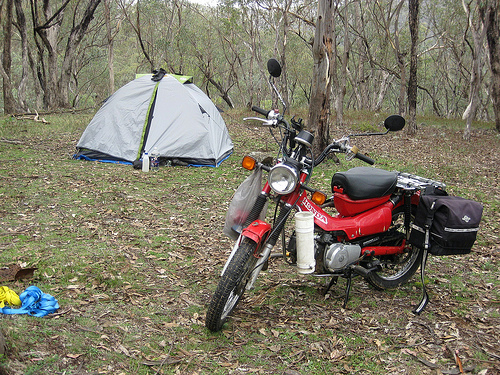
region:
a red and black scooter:
[175, 78, 494, 346]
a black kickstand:
[317, 269, 374, 326]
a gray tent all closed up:
[68, 55, 250, 209]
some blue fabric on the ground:
[2, 274, 71, 329]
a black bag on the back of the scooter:
[405, 177, 493, 275]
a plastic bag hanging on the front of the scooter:
[210, 140, 273, 253]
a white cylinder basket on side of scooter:
[286, 207, 328, 287]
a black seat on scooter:
[335, 158, 415, 208]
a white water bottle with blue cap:
[137, 147, 159, 175]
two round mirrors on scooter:
[251, 52, 433, 153]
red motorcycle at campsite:
[206, 52, 467, 357]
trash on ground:
[0, 257, 79, 318]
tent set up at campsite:
[74, 41, 234, 171]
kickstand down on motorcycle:
[175, 57, 483, 335]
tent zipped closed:
[76, 57, 236, 196]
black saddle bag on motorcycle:
[418, 181, 476, 279]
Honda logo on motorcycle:
[297, 195, 331, 225]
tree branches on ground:
[6, 108, 104, 127]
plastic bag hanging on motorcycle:
[221, 153, 273, 237]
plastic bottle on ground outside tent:
[141, 150, 153, 175]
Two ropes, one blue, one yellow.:
[0, 273, 63, 325]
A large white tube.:
[287, 206, 327, 281]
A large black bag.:
[415, 186, 486, 263]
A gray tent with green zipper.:
[66, 60, 236, 176]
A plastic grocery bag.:
[220, 150, 267, 236]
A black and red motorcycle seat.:
[328, 167, 397, 220]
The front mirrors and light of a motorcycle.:
[237, 41, 411, 206]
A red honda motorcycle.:
[154, 53, 496, 344]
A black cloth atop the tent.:
[150, 63, 168, 84]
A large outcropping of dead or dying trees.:
[1, 1, 116, 100]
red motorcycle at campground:
[201, 47, 478, 363]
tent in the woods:
[43, 36, 244, 179]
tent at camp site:
[63, 34, 241, 181]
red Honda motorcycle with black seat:
[194, 46, 498, 365]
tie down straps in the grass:
[1, 223, 71, 343]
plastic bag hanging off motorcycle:
[199, 133, 291, 295]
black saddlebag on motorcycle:
[404, 168, 491, 284]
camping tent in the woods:
[21, 16, 239, 209]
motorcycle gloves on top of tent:
[69, 32, 221, 103]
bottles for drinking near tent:
[113, 140, 183, 185]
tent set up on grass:
[74, 69, 245, 180]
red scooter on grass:
[192, 66, 497, 321]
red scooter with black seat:
[240, 92, 486, 304]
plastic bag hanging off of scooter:
[210, 123, 277, 263]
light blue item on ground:
[7, 271, 87, 344]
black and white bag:
[375, 158, 498, 275]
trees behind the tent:
[36, 14, 264, 167]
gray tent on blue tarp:
[85, 62, 232, 181]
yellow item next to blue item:
[3, 281, 55, 319]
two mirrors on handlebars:
[240, 36, 448, 183]